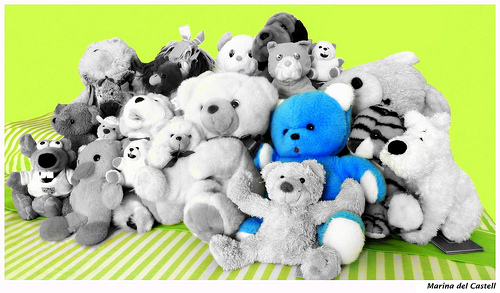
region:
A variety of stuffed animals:
[4, 12, 478, 276]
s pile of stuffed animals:
[40, 17, 476, 271]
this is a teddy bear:
[231, 81, 374, 249]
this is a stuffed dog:
[373, 96, 471, 256]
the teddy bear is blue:
[229, 92, 396, 254]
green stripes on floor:
[2, 210, 437, 290]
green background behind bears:
[9, 5, 497, 190]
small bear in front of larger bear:
[196, 84, 385, 279]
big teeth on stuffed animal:
[13, 122, 81, 224]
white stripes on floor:
[29, 208, 465, 286]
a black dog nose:
[383, 122, 418, 172]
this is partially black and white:
[31, 24, 348, 286]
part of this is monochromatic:
[97, 75, 226, 187]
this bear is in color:
[276, 98, 351, 165]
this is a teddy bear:
[280, 98, 333, 154]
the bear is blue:
[277, 86, 347, 168]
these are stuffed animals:
[65, 41, 329, 225]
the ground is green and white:
[62, 246, 182, 278]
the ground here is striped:
[88, 250, 166, 280]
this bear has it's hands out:
[231, 168, 371, 213]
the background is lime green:
[360, 16, 493, 69]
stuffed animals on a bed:
[5, 10, 480, 278]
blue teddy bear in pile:
[232, 82, 384, 266]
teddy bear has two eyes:
[281, 123, 315, 135]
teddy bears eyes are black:
[279, 122, 316, 135]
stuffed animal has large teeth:
[41, 170, 53, 178]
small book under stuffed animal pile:
[430, 231, 482, 254]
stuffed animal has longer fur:
[378, 110, 478, 246]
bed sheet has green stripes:
[4, 107, 494, 282]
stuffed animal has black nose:
[291, 134, 301, 139]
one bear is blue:
[212, 84, 389, 241]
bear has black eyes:
[252, 109, 315, 149]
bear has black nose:
[277, 134, 312, 148]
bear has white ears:
[274, 72, 346, 144]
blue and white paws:
[360, 155, 387, 210]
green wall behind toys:
[377, 10, 457, 87]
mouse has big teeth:
[25, 136, 73, 204]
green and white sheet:
[27, 214, 240, 271]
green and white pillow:
[2, 103, 89, 156]